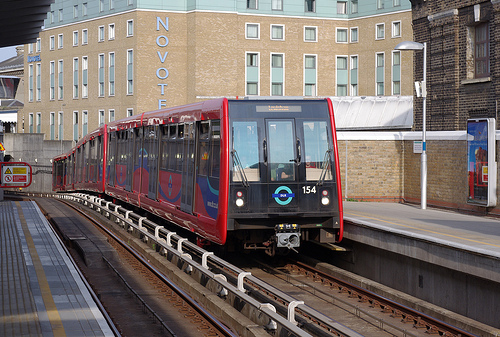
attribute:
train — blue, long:
[50, 91, 350, 256]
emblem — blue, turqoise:
[268, 184, 300, 208]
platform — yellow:
[11, 181, 81, 335]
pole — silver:
[396, 40, 429, 215]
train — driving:
[103, 99, 361, 264]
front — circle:
[225, 97, 343, 254]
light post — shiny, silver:
[395, 37, 431, 212]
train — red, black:
[158, 87, 364, 269]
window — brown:
[226, 106, 353, 209]